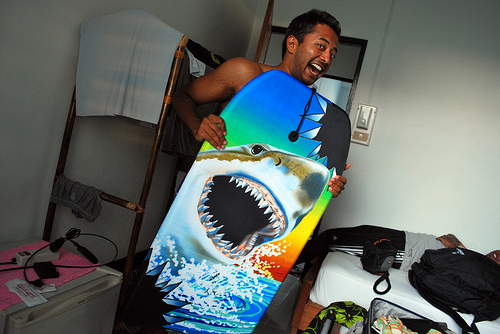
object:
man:
[172, 9, 350, 334]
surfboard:
[111, 69, 349, 334]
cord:
[1, 227, 120, 290]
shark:
[158, 142, 331, 267]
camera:
[361, 237, 399, 276]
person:
[293, 224, 500, 334]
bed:
[291, 228, 500, 333]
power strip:
[14, 248, 62, 265]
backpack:
[409, 247, 500, 326]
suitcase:
[366, 297, 456, 333]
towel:
[74, 11, 184, 124]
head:
[279, 9, 340, 84]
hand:
[196, 113, 229, 150]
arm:
[173, 56, 254, 127]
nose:
[320, 49, 331, 64]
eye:
[317, 44, 325, 49]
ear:
[286, 35, 298, 53]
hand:
[328, 163, 352, 198]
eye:
[330, 53, 336, 59]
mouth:
[307, 63, 324, 78]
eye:
[250, 144, 264, 154]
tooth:
[251, 188, 256, 194]